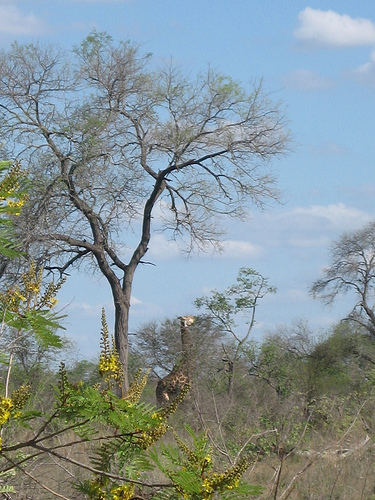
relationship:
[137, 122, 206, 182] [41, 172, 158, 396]
branch of a tree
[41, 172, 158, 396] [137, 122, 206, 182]
tree has a branch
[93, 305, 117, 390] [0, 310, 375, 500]
flowers on brush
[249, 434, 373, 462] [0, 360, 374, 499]
log fallen on ground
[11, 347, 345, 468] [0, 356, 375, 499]
brush growing on field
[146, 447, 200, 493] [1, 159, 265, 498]
leaf on bush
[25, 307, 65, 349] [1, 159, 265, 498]
leaf on bush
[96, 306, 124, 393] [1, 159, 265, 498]
flower on bush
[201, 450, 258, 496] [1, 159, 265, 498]
flower on bush